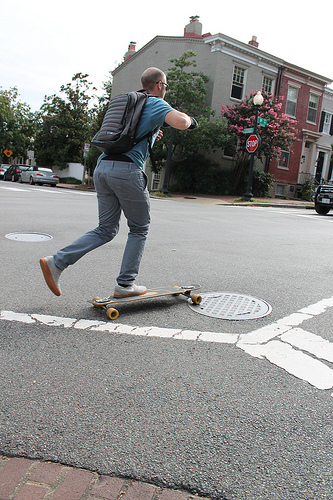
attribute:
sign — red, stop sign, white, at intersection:
[245, 134, 261, 156]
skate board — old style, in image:
[89, 282, 210, 321]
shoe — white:
[37, 254, 70, 304]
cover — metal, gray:
[191, 289, 274, 325]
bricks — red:
[2, 453, 231, 498]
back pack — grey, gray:
[90, 88, 145, 161]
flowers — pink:
[224, 90, 307, 153]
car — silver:
[13, 162, 60, 187]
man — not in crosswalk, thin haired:
[38, 64, 205, 304]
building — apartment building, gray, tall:
[100, 15, 331, 204]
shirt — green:
[96, 97, 177, 177]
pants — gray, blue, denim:
[50, 159, 155, 293]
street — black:
[0, 181, 332, 496]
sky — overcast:
[1, 2, 332, 116]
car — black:
[3, 161, 31, 186]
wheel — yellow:
[98, 307, 124, 325]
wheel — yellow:
[189, 294, 206, 309]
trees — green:
[3, 79, 270, 197]